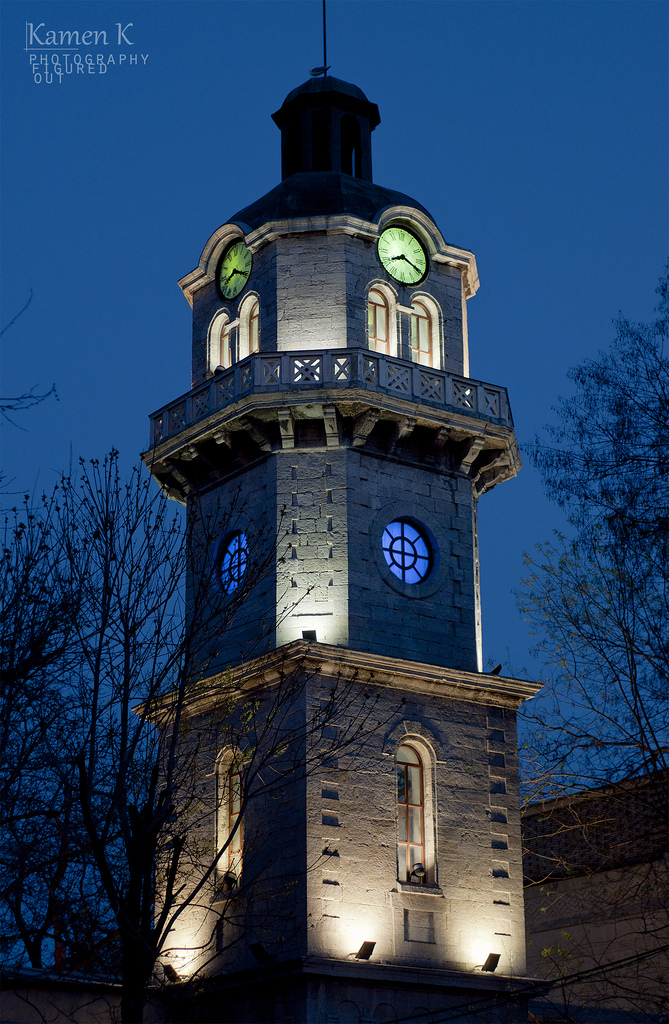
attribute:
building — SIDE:
[171, 98, 538, 1002]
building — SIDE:
[146, 85, 516, 1021]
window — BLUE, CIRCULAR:
[178, 531, 261, 596]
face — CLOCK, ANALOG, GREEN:
[379, 225, 433, 284]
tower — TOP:
[132, 29, 555, 1020]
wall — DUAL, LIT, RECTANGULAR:
[308, 650, 523, 962]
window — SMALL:
[385, 738, 440, 914]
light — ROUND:
[351, 925, 378, 962]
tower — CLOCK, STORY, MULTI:
[99, 104, 535, 1019]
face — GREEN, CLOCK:
[388, 227, 422, 289]